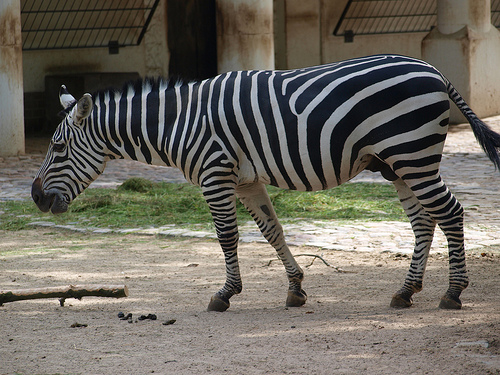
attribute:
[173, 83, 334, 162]
stripes — black, white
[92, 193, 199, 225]
grass — green, cut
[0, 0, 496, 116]
wall — white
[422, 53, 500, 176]
tail — long, bushy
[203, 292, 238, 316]
hoof — gray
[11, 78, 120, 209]
head — down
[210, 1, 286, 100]
column — stone, thick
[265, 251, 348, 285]
twig — small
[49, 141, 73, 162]
eye — black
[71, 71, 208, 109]
hair — spiked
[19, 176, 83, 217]
mouth — closed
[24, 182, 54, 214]
nose — black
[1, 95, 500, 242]
field — grassy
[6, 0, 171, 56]
rail — metal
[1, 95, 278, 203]
walkway — stone